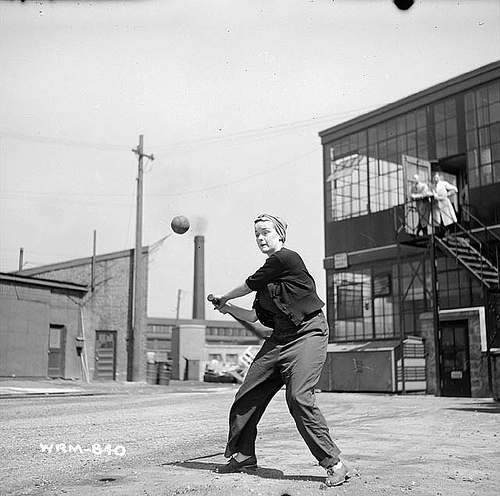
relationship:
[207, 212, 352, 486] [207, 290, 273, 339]
woman holding bat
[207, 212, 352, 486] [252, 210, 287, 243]
woman wearing bandana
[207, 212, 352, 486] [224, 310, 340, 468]
woman wearing pants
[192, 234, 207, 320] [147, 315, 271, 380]
smokestack on building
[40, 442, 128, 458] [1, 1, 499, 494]
wrm-840 on photo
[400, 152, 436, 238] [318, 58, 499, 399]
door into building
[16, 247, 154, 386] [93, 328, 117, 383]
building has door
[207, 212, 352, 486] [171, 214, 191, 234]
woman swinging at ball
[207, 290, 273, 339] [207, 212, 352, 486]
bat swung by woman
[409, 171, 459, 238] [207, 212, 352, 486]
people watching woman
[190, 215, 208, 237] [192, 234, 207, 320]
smoke coming from smokestack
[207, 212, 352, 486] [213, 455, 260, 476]
woman wearing shoe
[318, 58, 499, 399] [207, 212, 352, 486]
building behind woman